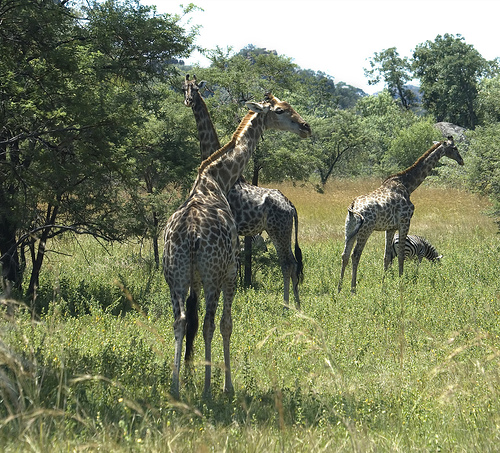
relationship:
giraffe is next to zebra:
[329, 126, 464, 308] [381, 225, 443, 274]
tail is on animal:
[182, 239, 203, 345] [143, 69, 318, 411]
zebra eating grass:
[381, 225, 443, 274] [2, 171, 499, 451]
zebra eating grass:
[381, 225, 443, 274] [331, 306, 483, 445]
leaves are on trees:
[7, 0, 177, 244] [20, 2, 123, 309]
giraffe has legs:
[131, 73, 457, 408] [164, 272, 239, 402]